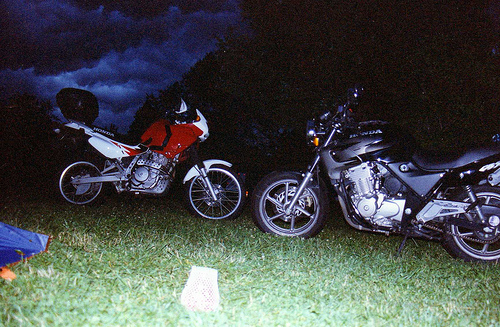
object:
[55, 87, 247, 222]
red honda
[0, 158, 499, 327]
parked on the grass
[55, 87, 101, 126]
mounted on the seat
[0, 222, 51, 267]
camping trip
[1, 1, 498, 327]
camp site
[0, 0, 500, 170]
mountains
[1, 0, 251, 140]
clouds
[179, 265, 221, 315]
lantern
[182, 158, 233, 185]
white fender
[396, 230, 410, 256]
motorcycle stand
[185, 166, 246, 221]
front wheel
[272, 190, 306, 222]
disk brake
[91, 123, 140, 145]
seat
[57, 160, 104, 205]
on the rear wheel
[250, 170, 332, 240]
front wheel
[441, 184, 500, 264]
rear wheel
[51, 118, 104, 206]
high clearance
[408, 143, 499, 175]
black seat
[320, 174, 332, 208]
black fender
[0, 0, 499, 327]
photo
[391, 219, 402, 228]
pedal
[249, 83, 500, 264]
both motorcycles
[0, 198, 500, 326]
grass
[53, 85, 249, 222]
motorcycle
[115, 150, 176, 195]
engine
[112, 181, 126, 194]
pedal